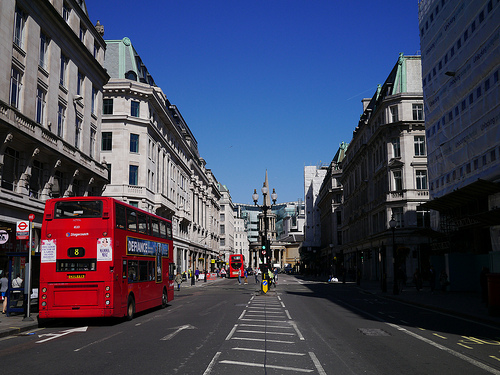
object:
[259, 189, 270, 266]
pole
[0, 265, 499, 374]
street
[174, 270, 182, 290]
person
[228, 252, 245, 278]
bus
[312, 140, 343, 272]
building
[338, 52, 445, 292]
building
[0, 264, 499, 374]
ground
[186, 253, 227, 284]
people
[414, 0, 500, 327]
building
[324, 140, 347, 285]
building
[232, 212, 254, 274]
building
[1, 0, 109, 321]
building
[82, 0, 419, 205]
sky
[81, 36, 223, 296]
building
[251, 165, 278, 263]
lamp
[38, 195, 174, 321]
bus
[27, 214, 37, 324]
pole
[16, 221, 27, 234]
sign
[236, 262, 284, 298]
people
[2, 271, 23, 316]
human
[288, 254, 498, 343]
shade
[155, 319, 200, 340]
arrow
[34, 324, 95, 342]
arrow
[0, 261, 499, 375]
road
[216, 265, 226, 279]
sign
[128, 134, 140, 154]
window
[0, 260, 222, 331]
sidewalk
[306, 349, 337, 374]
line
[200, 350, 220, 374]
line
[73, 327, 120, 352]
line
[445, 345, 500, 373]
line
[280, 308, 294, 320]
line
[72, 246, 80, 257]
number